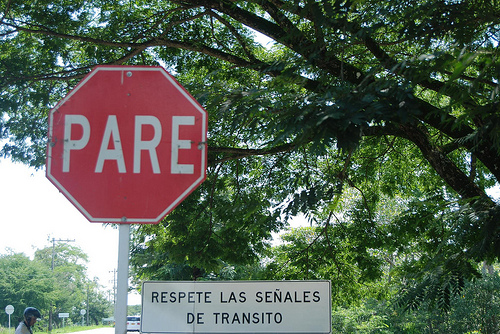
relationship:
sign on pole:
[45, 65, 208, 225] [114, 222, 136, 333]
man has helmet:
[13, 305, 38, 332] [25, 307, 43, 322]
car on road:
[125, 311, 142, 333] [71, 322, 142, 334]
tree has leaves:
[206, 0, 498, 329] [286, 71, 400, 148]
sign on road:
[45, 65, 208, 225] [71, 322, 142, 334]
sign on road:
[138, 278, 337, 332] [71, 322, 142, 334]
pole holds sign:
[114, 222, 136, 333] [45, 65, 208, 225]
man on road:
[13, 305, 38, 332] [71, 322, 142, 334]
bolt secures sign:
[123, 67, 135, 81] [45, 65, 208, 225]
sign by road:
[55, 309, 74, 322] [71, 322, 142, 334]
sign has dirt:
[45, 65, 208, 225] [45, 129, 71, 175]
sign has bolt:
[45, 65, 208, 225] [123, 67, 135, 81]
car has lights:
[125, 311, 142, 333] [135, 322, 141, 328]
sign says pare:
[45, 65, 208, 225] [58, 110, 198, 177]